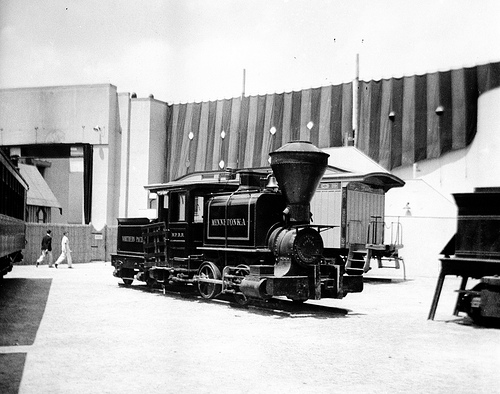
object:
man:
[36, 229, 56, 267]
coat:
[41, 235, 51, 251]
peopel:
[54, 231, 73, 268]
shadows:
[312, 302, 341, 317]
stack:
[266, 140, 329, 220]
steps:
[345, 248, 370, 278]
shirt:
[61, 236, 71, 253]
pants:
[36, 249, 53, 267]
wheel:
[195, 261, 222, 301]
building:
[0, 83, 169, 279]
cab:
[138, 190, 277, 253]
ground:
[125, 348, 180, 368]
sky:
[32, 23, 108, 52]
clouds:
[307, 10, 349, 22]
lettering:
[211, 217, 247, 227]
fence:
[161, 83, 339, 186]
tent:
[20, 162, 63, 208]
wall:
[56, 184, 73, 202]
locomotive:
[109, 139, 406, 312]